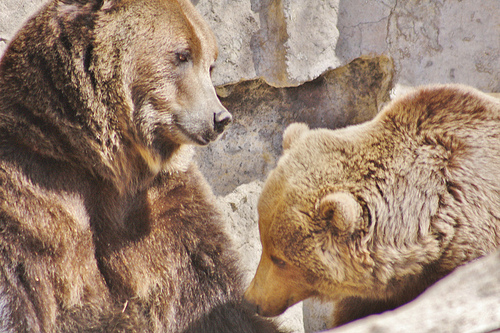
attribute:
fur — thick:
[19, 10, 302, 327]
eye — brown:
[269, 248, 286, 278]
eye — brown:
[169, 44, 195, 69]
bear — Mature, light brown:
[239, 76, 499, 320]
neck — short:
[346, 126, 446, 286]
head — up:
[249, 120, 389, 311]